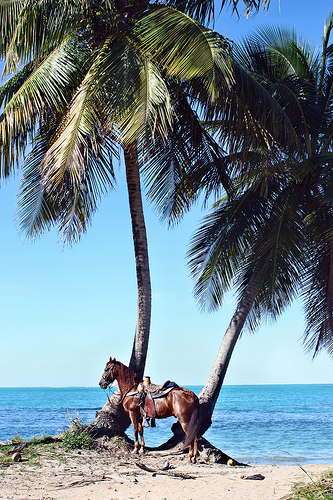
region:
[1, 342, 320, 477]
a gorgeous horse on a gorgeous beach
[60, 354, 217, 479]
the horse is saddled & ready to ride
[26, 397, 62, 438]
the water is very blue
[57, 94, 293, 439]
the palm trees are very tall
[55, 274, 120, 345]
the sky is clear as a bell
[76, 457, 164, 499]
the horse is on a sandy beach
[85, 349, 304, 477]
i would love to ride this horse on the beach!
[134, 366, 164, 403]
the saddle appears to be an "aussie" style -- the pommel is large .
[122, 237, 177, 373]
the palm tree is curved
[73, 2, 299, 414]
two palm tall palm trees are in the photo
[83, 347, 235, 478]
a full grown horse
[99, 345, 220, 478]
a horse wearing a saddle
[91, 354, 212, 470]
a horse wearing a bridle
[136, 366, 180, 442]
a leather western saddle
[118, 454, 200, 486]
dead palm leaves on ground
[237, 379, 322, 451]
bright blue ocean water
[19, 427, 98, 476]
patches of grass on beach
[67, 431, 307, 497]
a flat, sandy shore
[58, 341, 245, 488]
a horse standing on beach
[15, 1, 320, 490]
a pair of palm trees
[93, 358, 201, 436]
Brown horse next to ocean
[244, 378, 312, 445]
Clear, blue water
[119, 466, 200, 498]
Brown sand next to horse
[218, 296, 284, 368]
Palm tree above sand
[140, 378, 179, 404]
saddle on top of horse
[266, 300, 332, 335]
Green leaves on tree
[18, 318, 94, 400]
Clear blue sky behind ocean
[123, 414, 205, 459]
Four legs on horse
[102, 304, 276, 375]
Tow palm trees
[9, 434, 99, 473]
Green grass on sand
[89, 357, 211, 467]
brown horse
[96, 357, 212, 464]
brown horse with saddle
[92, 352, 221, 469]
brown horse with brown saddle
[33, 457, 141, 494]
gray sand with rocks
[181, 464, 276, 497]
gray sand near beach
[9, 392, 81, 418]
blue calm ocean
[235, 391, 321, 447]
blue calm ocean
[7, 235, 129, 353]
blue clear cloudless sky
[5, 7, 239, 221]
brown palm tree with green leaves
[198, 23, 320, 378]
brown palm tree with green leaves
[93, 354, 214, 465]
Horse on the beach with a saddle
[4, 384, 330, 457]
large expanse of open ocean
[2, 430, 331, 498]
sandy grassy beach front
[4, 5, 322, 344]
two large palm trees on the beach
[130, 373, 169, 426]
saddle for riding a horse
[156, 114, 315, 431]
smaller crooked palm tree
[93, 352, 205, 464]
horse wearing both saddle and bridle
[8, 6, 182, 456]
large tall palm tree on beach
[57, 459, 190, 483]
loose pieces of driftwood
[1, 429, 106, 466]
organic bushes